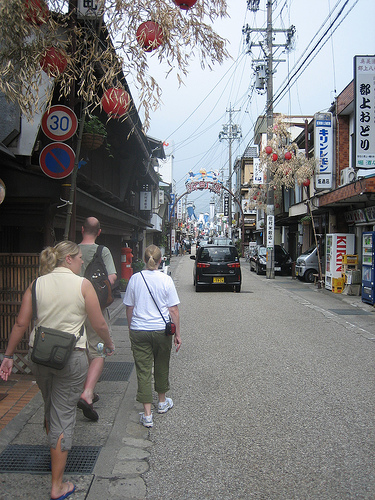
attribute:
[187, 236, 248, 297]
car — black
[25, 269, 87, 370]
bag — black, carried, behind, gray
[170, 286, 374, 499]
road — tarmac, grey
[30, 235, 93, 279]
hair — blonde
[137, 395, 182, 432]
shoes — white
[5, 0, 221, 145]
tree — brown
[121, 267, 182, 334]
t-shirt — white, red, black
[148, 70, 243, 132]
sky — blue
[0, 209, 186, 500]
people — walking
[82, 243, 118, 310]
bag — dark, crossbody, black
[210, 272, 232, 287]
license plate — yellow, black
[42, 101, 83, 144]
sign — red, white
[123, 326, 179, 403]
pants — green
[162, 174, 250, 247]
structure — semicircular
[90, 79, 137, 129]
ball — red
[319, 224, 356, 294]
machine — red, white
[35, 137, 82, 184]
sign — round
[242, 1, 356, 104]
wires — thick